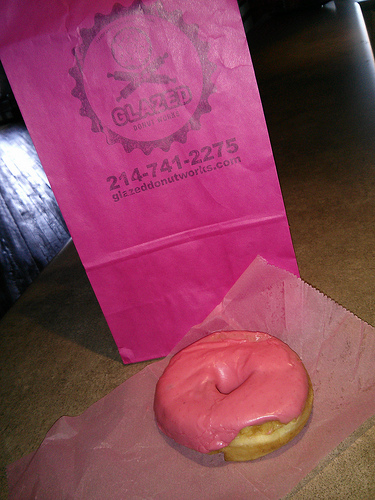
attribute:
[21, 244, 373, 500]
paper — waxed, pink, wax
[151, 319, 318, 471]
donut — glazed, pink, circular, pretty, brown, strawberry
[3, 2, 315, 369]
bag — pink, paper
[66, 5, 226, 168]
logo — graphic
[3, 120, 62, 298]
wood — shiny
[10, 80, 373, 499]
countertop — brown